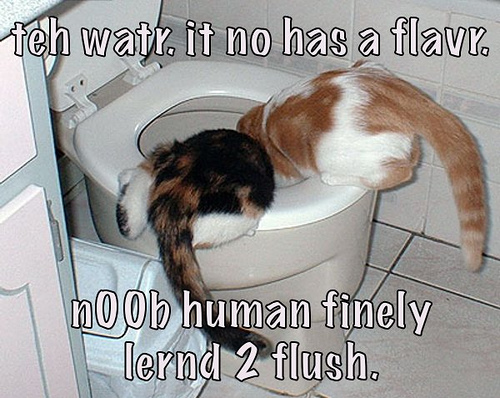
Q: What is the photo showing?
A: It is showing a bathroom.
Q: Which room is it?
A: It is a bathroom.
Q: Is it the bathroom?
A: Yes, it is the bathroom.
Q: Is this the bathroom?
A: Yes, it is the bathroom.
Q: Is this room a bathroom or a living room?
A: It is a bathroom.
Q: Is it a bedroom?
A: No, it is a bathroom.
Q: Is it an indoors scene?
A: Yes, it is indoors.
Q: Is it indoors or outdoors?
A: It is indoors.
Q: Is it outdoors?
A: No, it is indoors.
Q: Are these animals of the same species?
A: Yes, all the animals are cats.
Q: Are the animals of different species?
A: No, all the animals are cats.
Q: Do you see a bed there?
A: No, there are no beds.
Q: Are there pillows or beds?
A: No, there are no beds or pillows.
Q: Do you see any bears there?
A: No, there are no bears.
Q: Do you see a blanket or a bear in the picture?
A: No, there are no bears or blankets.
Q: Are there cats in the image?
A: Yes, there is a cat.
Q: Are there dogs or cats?
A: Yes, there is a cat.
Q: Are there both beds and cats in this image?
A: No, there is a cat but no beds.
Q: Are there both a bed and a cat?
A: No, there is a cat but no beds.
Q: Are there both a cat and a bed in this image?
A: No, there is a cat but no beds.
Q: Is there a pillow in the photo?
A: No, there are no pillows.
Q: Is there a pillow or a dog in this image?
A: No, there are no pillows or dogs.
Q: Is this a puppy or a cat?
A: This is a cat.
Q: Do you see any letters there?
A: Yes, there are letters.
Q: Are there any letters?
A: Yes, there are letters.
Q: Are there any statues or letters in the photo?
A: Yes, there are letters.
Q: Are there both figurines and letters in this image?
A: No, there are letters but no figurines.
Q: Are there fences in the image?
A: No, there are no fences.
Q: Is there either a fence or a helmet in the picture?
A: No, there are no fences or helmets.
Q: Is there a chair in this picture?
A: No, there are no chairs.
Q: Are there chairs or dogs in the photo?
A: No, there are no chairs or dogs.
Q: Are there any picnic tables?
A: No, there are no picnic tables.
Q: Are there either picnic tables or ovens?
A: No, there are no picnic tables or ovens.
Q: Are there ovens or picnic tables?
A: No, there are no picnic tables or ovens.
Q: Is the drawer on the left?
A: Yes, the drawer is on the left of the image.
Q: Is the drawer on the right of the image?
A: No, the drawer is on the left of the image.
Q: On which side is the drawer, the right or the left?
A: The drawer is on the left of the image.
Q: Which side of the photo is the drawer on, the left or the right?
A: The drawer is on the left of the image.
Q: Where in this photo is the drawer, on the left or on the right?
A: The drawer is on the left of the image.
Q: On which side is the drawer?
A: The drawer is on the left of the image.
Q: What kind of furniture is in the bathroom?
A: The piece of furniture is a drawer.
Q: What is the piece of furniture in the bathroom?
A: The piece of furniture is a drawer.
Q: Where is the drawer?
A: The drawer is in the bathroom.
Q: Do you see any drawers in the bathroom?
A: Yes, there is a drawer in the bathroom.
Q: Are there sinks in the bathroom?
A: No, there is a drawer in the bathroom.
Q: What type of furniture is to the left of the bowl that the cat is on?
A: The piece of furniture is a drawer.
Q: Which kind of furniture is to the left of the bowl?
A: The piece of furniture is a drawer.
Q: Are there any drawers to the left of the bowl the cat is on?
A: Yes, there is a drawer to the left of the bowl.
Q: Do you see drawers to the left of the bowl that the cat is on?
A: Yes, there is a drawer to the left of the bowl.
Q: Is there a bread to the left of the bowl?
A: No, there is a drawer to the left of the bowl.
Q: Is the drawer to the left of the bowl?
A: Yes, the drawer is to the left of the bowl.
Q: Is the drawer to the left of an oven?
A: No, the drawer is to the left of the bowl.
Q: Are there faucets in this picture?
A: No, there are no faucets.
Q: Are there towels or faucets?
A: No, there are no faucets or towels.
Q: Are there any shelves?
A: No, there are no shelves.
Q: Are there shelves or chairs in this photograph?
A: No, there are no shelves or chairs.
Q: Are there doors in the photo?
A: Yes, there is a door.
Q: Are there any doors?
A: Yes, there is a door.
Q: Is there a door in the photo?
A: Yes, there is a door.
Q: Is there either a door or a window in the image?
A: Yes, there is a door.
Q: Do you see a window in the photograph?
A: No, there are no windows.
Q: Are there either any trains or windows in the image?
A: No, there are no windows or trains.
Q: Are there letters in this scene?
A: Yes, there are letters.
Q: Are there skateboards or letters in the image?
A: Yes, there are letters.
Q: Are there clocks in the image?
A: No, there are no clocks.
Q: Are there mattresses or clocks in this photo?
A: No, there are no clocks or mattresses.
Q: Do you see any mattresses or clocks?
A: No, there are no clocks or mattresses.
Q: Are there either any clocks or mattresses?
A: No, there are no clocks or mattresses.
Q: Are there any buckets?
A: No, there are no buckets.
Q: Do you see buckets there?
A: No, there are no buckets.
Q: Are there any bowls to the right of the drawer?
A: Yes, there is a bowl to the right of the drawer.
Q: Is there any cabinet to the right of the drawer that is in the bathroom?
A: No, there is a bowl to the right of the drawer.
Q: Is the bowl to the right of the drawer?
A: Yes, the bowl is to the right of the drawer.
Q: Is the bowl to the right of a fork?
A: No, the bowl is to the right of the drawer.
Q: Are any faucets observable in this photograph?
A: No, there are no faucets.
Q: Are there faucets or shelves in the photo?
A: No, there are no faucets or shelves.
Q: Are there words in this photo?
A: Yes, there are words.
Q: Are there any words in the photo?
A: Yes, there are words.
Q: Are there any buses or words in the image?
A: Yes, there are words.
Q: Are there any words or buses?
A: Yes, there are words.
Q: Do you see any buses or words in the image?
A: Yes, there are words.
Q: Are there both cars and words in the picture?
A: No, there are words but no cars.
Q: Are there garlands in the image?
A: No, there are no garlands.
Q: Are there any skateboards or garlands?
A: No, there are no garlands or skateboards.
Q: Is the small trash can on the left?
A: Yes, the trash can is on the left of the image.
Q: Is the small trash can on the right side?
A: No, the trash bin is on the left of the image.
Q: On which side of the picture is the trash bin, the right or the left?
A: The trash bin is on the left of the image.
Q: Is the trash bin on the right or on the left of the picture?
A: The trash bin is on the left of the image.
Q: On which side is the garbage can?
A: The garbage can is on the left of the image.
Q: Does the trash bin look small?
A: Yes, the trash bin is small.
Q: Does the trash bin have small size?
A: Yes, the trash bin is small.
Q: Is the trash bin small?
A: Yes, the trash bin is small.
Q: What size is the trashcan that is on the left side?
A: The trashcan is small.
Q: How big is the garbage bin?
A: The garbage bin is small.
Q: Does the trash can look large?
A: No, the trash can is small.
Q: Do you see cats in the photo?
A: Yes, there is a cat.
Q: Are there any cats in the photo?
A: Yes, there is a cat.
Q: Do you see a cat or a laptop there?
A: Yes, there is a cat.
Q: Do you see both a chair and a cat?
A: No, there is a cat but no chairs.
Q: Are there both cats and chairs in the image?
A: No, there is a cat but no chairs.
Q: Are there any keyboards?
A: No, there are no keyboards.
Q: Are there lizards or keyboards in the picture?
A: No, there are no keyboards or lizards.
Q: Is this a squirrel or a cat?
A: This is a cat.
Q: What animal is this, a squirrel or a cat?
A: This is a cat.